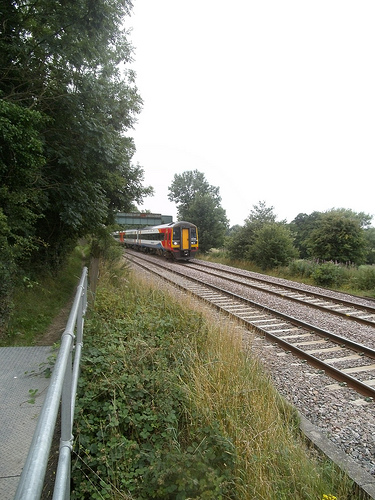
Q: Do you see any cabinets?
A: No, there are no cabinets.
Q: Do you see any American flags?
A: No, there are no American flags.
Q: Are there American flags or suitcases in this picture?
A: No, there are no American flags or suitcases.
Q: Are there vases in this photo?
A: No, there are no vases.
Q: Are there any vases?
A: No, there are no vases.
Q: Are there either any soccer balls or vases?
A: No, there are no vases or soccer balls.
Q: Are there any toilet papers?
A: No, there are no toilet papers.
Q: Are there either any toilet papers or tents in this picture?
A: No, there are no toilet papers or tents.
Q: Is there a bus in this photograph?
A: No, there are no buses.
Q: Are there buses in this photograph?
A: No, there are no buses.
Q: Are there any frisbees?
A: No, there are no frisbees.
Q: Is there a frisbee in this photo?
A: No, there are no frisbees.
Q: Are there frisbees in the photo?
A: No, there are no frisbees.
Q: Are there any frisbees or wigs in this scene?
A: No, there are no frisbees or wigs.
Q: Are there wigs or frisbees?
A: No, there are no frisbees or wigs.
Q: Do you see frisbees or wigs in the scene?
A: No, there are no frisbees or wigs.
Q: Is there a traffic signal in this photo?
A: No, there are no traffic lights.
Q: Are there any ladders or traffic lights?
A: No, there are no traffic lights or ladders.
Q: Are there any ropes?
A: No, there are no ropes.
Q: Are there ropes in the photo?
A: No, there are no ropes.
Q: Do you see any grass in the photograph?
A: Yes, there is grass.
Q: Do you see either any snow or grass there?
A: Yes, there is grass.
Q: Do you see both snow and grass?
A: No, there is grass but no snow.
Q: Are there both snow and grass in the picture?
A: No, there is grass but no snow.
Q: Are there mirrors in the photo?
A: No, there are no mirrors.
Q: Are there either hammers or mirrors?
A: No, there are no mirrors or hammers.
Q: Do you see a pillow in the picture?
A: No, there are no pillows.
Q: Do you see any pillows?
A: No, there are no pillows.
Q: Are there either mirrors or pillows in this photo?
A: No, there are no pillows or mirrors.